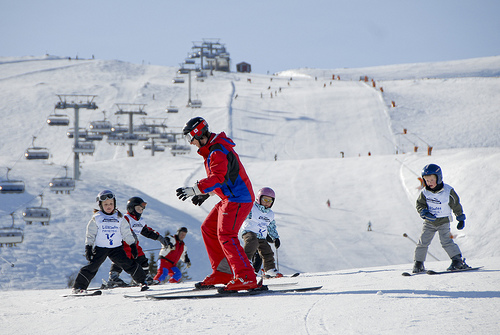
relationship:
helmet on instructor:
[176, 109, 215, 145] [175, 116, 261, 292]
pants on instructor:
[209, 215, 287, 293] [175, 116, 261, 292]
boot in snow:
[209, 243, 263, 293] [254, 297, 346, 317]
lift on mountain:
[91, 49, 220, 130] [84, 39, 387, 149]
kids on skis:
[80, 196, 166, 270] [146, 267, 292, 314]